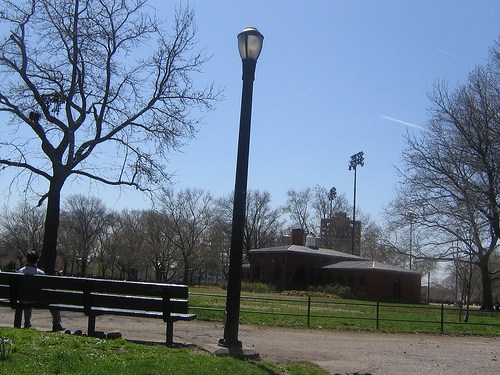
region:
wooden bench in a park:
[2, 265, 197, 332]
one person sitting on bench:
[22, 241, 66, 333]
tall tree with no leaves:
[13, 0, 194, 268]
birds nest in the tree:
[15, 100, 50, 136]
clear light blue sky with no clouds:
[295, 19, 400, 61]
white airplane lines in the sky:
[371, 103, 461, 138]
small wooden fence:
[280, 296, 470, 328]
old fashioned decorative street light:
[215, 21, 287, 362]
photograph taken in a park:
[37, 17, 498, 356]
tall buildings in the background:
[313, 206, 370, 259]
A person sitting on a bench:
[20, 249, 42, 299]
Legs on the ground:
[23, 310, 63, 330]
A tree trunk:
[45, 223, 52, 257]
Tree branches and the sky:
[66, 100, 83, 124]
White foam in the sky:
[391, 120, 403, 123]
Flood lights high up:
[348, 154, 362, 164]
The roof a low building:
[282, 247, 307, 250]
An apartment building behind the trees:
[327, 220, 347, 246]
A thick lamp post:
[235, 185, 242, 237]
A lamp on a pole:
[239, 25, 259, 59]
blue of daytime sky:
[0, 1, 499, 189]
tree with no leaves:
[0, 2, 226, 270]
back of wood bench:
[0, 270, 195, 341]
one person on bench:
[0, 250, 195, 342]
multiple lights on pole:
[343, 150, 364, 216]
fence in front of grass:
[243, 296, 498, 331]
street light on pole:
[216, 26, 264, 348]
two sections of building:
[250, 242, 421, 302]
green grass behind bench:
[1, 272, 198, 373]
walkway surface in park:
[2, 289, 497, 373]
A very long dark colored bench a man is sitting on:
[1, 268, 197, 347]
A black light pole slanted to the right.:
[218, 27, 263, 346]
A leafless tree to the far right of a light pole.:
[381, 58, 499, 308]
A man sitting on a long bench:
[18, 246, 65, 331]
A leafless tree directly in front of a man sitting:
[0, 0, 228, 275]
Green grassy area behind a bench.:
[2, 326, 315, 373]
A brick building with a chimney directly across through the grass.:
[238, 225, 422, 307]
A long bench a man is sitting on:
[3, 268, 196, 349]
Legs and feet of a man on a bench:
[20, 307, 65, 332]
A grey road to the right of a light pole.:
[244, 322, 497, 374]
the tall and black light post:
[218, 16, 265, 348]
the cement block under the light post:
[199, 342, 259, 359]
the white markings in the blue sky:
[296, 45, 465, 130]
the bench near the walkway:
[0, 269, 198, 346]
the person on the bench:
[20, 248, 65, 331]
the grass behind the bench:
[1, 324, 331, 374]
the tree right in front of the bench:
[0, 0, 227, 272]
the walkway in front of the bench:
[0, 305, 497, 374]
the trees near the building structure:
[1, 40, 498, 307]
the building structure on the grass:
[241, 227, 422, 306]